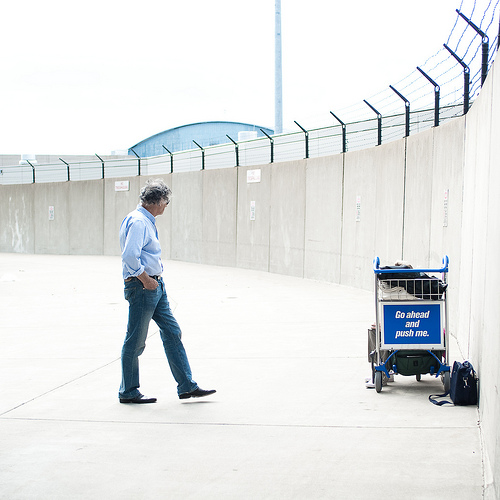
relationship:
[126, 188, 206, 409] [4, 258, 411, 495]
man in ground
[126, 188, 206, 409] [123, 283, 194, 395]
man wears jeans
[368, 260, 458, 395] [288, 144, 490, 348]
cart parked against wall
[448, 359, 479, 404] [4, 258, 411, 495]
bag on ground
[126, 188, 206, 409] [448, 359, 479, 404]
man has bag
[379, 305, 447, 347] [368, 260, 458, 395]
sign on cart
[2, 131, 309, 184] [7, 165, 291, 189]
wire across wall top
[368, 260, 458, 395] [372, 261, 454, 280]
cart has handle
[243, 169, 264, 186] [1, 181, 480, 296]
sign on wall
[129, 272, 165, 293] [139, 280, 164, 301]
hands in pocket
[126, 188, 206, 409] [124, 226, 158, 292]
man with hand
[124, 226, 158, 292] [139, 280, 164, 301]
hand in pocket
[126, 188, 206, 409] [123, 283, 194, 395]
man on jeans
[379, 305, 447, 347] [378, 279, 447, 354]
sign on cart back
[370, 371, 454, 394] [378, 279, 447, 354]
wheel on cart back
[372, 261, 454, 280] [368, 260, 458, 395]
handle on cart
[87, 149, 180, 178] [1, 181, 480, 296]
rods over wall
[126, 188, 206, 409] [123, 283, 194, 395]
man in jeans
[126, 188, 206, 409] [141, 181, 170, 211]
man with hair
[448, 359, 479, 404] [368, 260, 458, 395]
bag next cart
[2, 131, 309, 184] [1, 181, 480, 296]
wire on wall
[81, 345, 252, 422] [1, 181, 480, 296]
walking along wall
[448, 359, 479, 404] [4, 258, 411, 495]
brief case on ground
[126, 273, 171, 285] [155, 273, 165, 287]
belt with buckle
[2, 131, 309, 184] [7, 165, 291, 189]
wire on wall top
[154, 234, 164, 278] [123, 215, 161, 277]
button on shirt